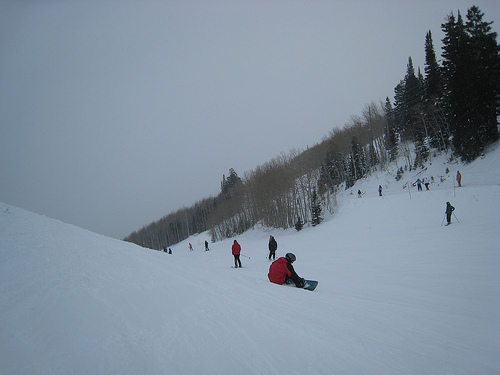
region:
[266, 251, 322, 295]
A fallen snow boarder.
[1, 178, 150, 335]
A mountain of white snow.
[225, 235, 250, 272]
A skier in red.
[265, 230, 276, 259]
A hiker in the distance.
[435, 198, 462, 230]
A skier in blue or black.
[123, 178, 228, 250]
An outcropping of dead trees against the skyline.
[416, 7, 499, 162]
An outcropping of living fir trees.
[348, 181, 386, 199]
Two skiers in the distance.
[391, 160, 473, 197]
A group of three people, walking or skiing along the path.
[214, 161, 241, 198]
The top of a large tree sticking up through the wooded area.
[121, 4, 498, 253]
Most of the trees have no leaves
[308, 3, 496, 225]
Trees on the right are green pine trees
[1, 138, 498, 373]
Snow is white and hilly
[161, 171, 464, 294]
People are skiing and snowboarding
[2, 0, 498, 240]
The sky is gray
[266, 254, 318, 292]
Snowboarder jacket is red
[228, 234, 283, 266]
Skiers standing and talking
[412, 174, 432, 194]
Person in blue jacket next to person in white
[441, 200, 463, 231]
skier is holding ski poles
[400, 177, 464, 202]
Two poles stuck in the ground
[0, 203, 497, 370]
a snow covered ski slope.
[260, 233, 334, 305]
a man sitting down in the snow.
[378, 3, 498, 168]
a forest filled with green trees.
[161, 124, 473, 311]
a crowded snow covered slope.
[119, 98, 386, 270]
a forest of leafless trees.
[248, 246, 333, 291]
a man sitting down on the snow.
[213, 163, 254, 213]
a tree in the middle of a forest.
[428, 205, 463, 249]
a person dressed to ski.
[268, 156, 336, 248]
a bunch of leafless trees.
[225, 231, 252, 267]
a person standing in the snow.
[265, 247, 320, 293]
person in a red jacket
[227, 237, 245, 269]
person in a red jacket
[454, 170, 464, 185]
person in a red jacket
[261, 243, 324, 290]
person sitting on the snow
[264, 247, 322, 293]
person on a snowboard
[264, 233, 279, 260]
person on some skis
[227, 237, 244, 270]
person on some skis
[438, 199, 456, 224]
person on some skis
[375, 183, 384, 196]
person on some skis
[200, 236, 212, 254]
person on some skis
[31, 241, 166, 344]
The snow is white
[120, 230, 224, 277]
The people are skiing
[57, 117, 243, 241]
The sky is cloudy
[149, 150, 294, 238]
The trees are bare and tall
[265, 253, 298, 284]
The person's jacket is red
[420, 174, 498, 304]
The person is standing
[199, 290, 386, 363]
The snow has tracks in it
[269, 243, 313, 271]
The person has a helmet on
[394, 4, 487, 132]
The trees are green and tall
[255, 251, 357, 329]
The person is sitting